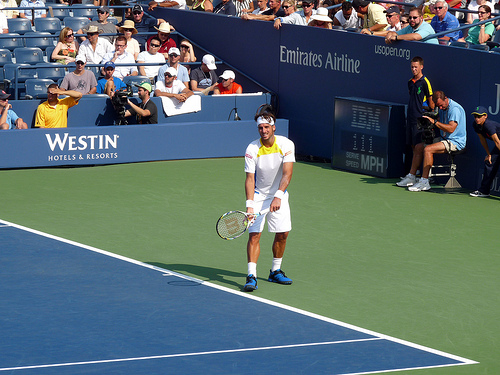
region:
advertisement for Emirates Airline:
[253, 36, 381, 91]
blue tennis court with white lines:
[0, 211, 499, 373]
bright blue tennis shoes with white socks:
[241, 256, 297, 290]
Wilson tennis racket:
[210, 204, 279, 241]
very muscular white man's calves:
[246, 228, 291, 263]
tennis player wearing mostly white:
[214, 99, 304, 301]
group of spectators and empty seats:
[0, 0, 268, 106]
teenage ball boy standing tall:
[405, 53, 435, 205]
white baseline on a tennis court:
[0, 211, 485, 366]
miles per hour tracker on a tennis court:
[322, 78, 397, 193]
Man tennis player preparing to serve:
[241, 107, 296, 292]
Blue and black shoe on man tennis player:
[240, 271, 256, 291]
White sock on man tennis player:
[245, 260, 256, 276]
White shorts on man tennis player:
[243, 192, 288, 232]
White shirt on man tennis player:
[245, 135, 296, 192]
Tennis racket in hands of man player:
[215, 207, 280, 240]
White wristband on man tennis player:
[270, 188, 285, 199]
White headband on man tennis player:
[251, 115, 276, 123]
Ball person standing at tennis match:
[405, 56, 433, 151]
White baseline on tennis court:
[0, 217, 480, 364]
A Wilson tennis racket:
[213, 205, 285, 242]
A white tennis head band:
[248, 113, 283, 128]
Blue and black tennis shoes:
[235, 263, 299, 297]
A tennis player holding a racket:
[209, 102, 303, 298]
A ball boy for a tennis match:
[464, 90, 498, 202]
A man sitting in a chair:
[391, 86, 471, 200]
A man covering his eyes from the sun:
[25, 80, 90, 137]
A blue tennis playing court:
[8, 308, 370, 371]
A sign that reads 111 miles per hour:
[326, 92, 406, 182]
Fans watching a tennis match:
[266, 2, 462, 44]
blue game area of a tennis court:
[3, 212, 467, 374]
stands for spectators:
[0, 1, 497, 176]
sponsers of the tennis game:
[266, 36, 413, 164]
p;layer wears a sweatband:
[253, 105, 291, 140]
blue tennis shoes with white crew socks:
[233, 253, 319, 298]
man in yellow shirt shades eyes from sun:
[28, 81, 85, 135]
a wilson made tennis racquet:
[208, 197, 287, 248]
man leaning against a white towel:
[154, 63, 205, 123]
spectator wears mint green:
[461, 2, 494, 53]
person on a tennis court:
[208, 103, 304, 298]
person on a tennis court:
[388, 87, 473, 198]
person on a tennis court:
[396, 51, 436, 169]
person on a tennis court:
[463, 98, 498, 207]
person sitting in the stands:
[211, 67, 248, 97]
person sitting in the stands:
[185, 52, 220, 99]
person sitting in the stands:
[56, 49, 99, 98]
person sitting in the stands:
[30, 78, 83, 130]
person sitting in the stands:
[113, 18, 143, 56]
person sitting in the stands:
[50, 19, 81, 64]